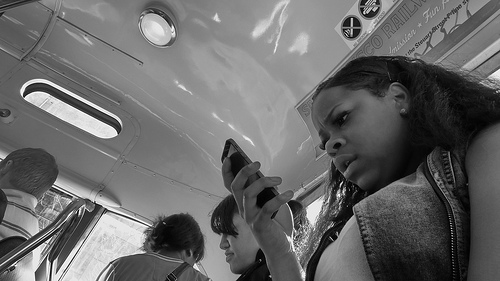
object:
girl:
[218, 56, 499, 280]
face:
[308, 81, 411, 193]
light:
[133, 8, 177, 49]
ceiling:
[0, 0, 402, 179]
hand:
[221, 155, 295, 250]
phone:
[219, 138, 276, 221]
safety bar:
[0, 198, 87, 271]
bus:
[1, 0, 500, 281]